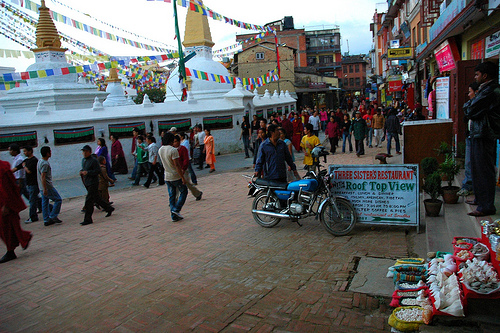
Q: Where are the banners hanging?
A: Above the street.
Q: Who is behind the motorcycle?
A: Man in long sleeved blue shirt.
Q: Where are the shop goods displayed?
A: On the steps.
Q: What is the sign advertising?
A: Restaurant.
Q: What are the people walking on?
A: The road.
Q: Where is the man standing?
A: Next to the motorcycle.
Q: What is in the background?
A: Buildings.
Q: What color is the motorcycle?
A: Blue.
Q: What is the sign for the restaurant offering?
A: A roof top view.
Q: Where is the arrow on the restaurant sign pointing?
A: To the right.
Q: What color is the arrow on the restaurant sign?
A: Green.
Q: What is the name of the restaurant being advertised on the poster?
A: Three Sisters Restaurant.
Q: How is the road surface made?
A: With bricks.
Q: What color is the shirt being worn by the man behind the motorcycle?
A: Blue.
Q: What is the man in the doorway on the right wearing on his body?
A: A leather jacket.